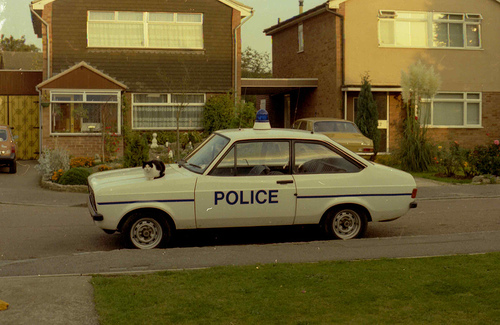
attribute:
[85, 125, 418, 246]
car — parked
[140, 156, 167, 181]
cat — black, white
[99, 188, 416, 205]
stripe — black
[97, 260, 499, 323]
grass — short , green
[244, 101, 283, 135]
light — blue 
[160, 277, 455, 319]
grass — green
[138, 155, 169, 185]
cat — black, white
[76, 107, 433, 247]
police car — parked, white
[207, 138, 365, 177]
windows — rolled up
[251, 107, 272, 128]
siren — blue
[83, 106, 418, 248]
car — white, unoccupied, black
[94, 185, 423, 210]
stripe — Blue 